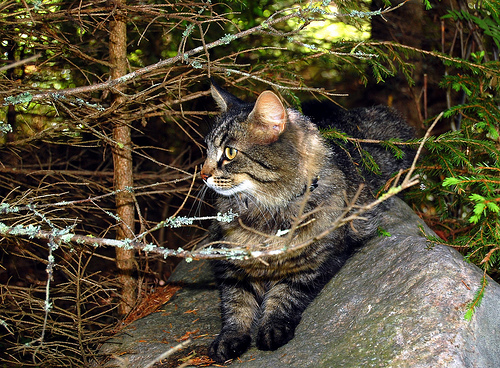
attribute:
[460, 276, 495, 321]
pine needles — fallen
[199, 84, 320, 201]
fur — striped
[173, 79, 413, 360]
cat — striped, laying, grey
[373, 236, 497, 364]
rock — large